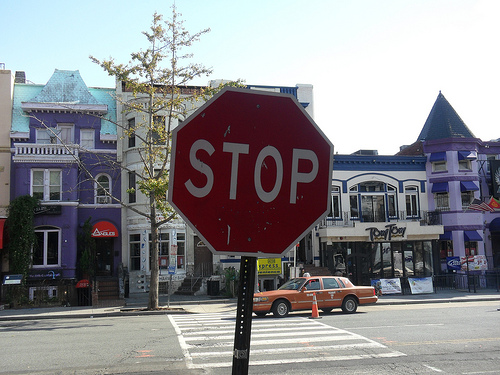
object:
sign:
[167, 88, 336, 257]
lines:
[195, 346, 407, 371]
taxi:
[251, 274, 380, 318]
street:
[0, 300, 499, 375]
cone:
[309, 293, 322, 319]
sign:
[257, 257, 282, 276]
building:
[216, 83, 314, 295]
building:
[308, 155, 444, 297]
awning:
[90, 221, 118, 238]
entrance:
[94, 235, 116, 277]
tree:
[24, 3, 249, 308]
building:
[116, 77, 211, 297]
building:
[415, 88, 484, 290]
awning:
[430, 152, 446, 162]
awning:
[458, 150, 477, 160]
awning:
[464, 230, 482, 242]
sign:
[381, 277, 402, 294]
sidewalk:
[374, 290, 500, 307]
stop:
[184, 139, 322, 206]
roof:
[416, 90, 477, 140]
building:
[15, 70, 123, 307]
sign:
[460, 255, 474, 265]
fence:
[188, 261, 213, 291]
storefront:
[328, 240, 436, 295]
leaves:
[93, 56, 161, 92]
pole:
[225, 257, 257, 374]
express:
[258, 263, 278, 269]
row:
[0, 65, 497, 306]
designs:
[91, 228, 116, 237]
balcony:
[14, 143, 80, 165]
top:
[9, 70, 119, 132]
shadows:
[0, 315, 114, 336]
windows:
[434, 161, 447, 172]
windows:
[458, 159, 471, 171]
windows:
[466, 242, 477, 256]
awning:
[431, 183, 450, 193]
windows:
[436, 192, 448, 212]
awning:
[461, 181, 479, 192]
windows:
[462, 192, 472, 206]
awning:
[439, 230, 452, 241]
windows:
[440, 240, 453, 258]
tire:
[343, 296, 358, 314]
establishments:
[0, 63, 498, 311]